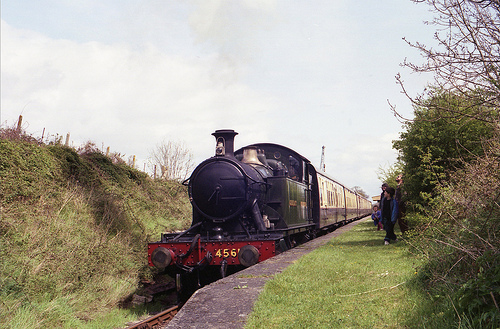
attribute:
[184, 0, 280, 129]
smoke — black, faint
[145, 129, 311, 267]
engine — steam, large, black, old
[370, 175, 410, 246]
people — standing, waiting, walking, small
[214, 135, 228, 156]
bell — metal, large, silver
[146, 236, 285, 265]
cow catcher — red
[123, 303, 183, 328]
train track — rusty, metal, brown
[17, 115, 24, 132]
fence post — wooden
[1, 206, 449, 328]
grass — green, growing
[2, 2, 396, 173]
background — blue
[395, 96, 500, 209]
trees — green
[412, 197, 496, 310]
shrubs — green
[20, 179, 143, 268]
weeds — brown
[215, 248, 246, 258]
numbers — yellow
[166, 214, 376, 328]
path — grey, concrete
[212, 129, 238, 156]
smoke stack — metal, black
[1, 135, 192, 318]
hillside — covered, small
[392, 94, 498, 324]
bushes — green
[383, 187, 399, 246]
person — looking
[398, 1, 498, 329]
tree — bare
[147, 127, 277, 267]
front of train — view, black, red